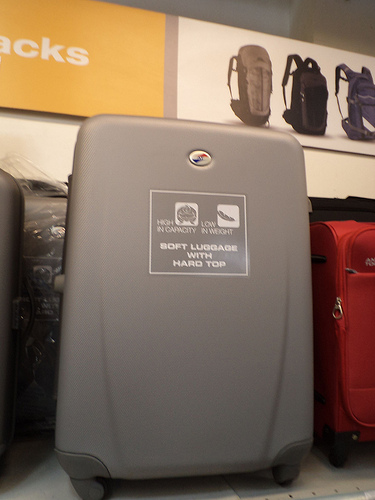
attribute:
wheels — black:
[323, 449, 354, 471]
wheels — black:
[93, 477, 114, 499]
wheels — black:
[267, 474, 297, 491]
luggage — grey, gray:
[47, 104, 323, 497]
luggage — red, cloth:
[311, 214, 375, 475]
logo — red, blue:
[180, 144, 223, 171]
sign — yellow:
[3, 0, 172, 125]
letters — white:
[3, 30, 101, 70]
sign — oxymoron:
[169, 9, 373, 167]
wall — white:
[1, 2, 374, 204]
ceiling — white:
[111, 1, 373, 53]